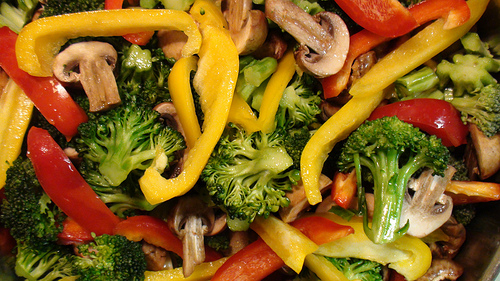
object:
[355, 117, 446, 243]
brocolli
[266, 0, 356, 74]
mushroom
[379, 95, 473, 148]
pepper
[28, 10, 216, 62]
pepper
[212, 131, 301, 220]
broccoli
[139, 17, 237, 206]
bell pepper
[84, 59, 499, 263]
vegetables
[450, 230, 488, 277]
pan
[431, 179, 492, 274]
corner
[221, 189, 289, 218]
florets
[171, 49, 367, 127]
stir fry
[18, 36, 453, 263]
salad